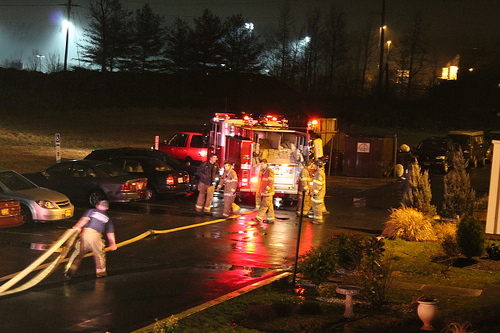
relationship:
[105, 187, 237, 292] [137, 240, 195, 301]
hose on ground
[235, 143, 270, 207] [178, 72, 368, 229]
light on truck